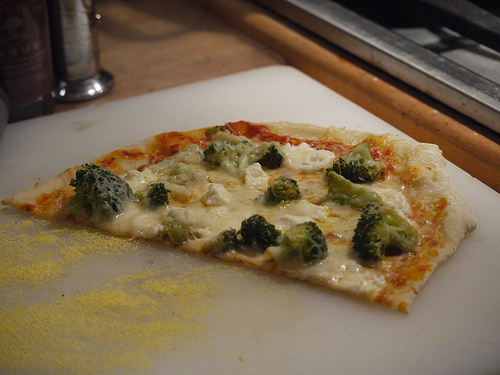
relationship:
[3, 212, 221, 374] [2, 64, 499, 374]
seasonings on plate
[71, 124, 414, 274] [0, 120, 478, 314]
broccoli on cheese topping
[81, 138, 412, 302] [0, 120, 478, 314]
cheese topping of cheese topping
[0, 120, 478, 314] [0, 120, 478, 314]
cheese topping of cheese topping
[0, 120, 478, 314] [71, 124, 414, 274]
cheese topping topped with broccoli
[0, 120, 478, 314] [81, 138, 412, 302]
cheese topping topped with cheese topping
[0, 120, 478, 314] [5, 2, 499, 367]
cheese topping on table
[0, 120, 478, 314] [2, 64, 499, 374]
cheese topping on plate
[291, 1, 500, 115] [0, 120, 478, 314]
bar next to cheese topping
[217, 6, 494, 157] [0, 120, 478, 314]
bar next to cheese topping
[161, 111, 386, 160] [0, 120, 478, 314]
tomato sauce on a cheese topping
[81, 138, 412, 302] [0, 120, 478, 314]
cheese topping on cheese topping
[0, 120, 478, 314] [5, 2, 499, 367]
cheese topping on a table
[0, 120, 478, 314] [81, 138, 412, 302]
cheese topping with cheese topping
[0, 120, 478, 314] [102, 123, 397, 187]
cheese topping with sauce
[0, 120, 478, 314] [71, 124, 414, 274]
cheese topping with broccoli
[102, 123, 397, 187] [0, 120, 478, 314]
sauce on cheese topping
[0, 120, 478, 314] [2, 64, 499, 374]
cheese topping on a plate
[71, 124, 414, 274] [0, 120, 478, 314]
broccoli topping on cheese topping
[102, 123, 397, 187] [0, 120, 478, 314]
sauce covering cheese topping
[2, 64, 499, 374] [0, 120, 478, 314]
plate under cheese topping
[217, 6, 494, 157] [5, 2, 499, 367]
bar on table